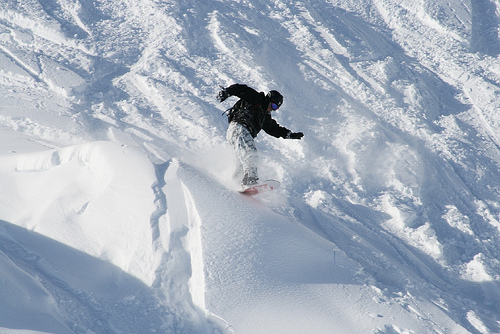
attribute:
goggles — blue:
[274, 95, 285, 109]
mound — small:
[10, 135, 320, 316]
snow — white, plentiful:
[1, 1, 500, 330]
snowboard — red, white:
[237, 177, 279, 201]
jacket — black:
[214, 83, 295, 140]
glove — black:
[289, 131, 304, 140]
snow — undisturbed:
[189, 181, 356, 332]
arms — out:
[217, 83, 307, 143]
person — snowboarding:
[212, 81, 305, 197]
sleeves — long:
[220, 81, 261, 102]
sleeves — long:
[261, 117, 295, 138]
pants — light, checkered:
[225, 121, 261, 187]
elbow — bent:
[229, 79, 248, 100]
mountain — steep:
[1, 2, 500, 332]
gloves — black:
[216, 86, 307, 140]